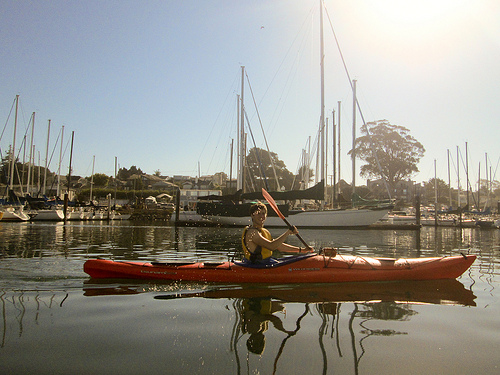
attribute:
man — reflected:
[236, 201, 317, 263]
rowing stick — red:
[264, 182, 314, 254]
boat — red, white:
[84, 250, 480, 284]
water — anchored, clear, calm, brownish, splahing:
[7, 210, 499, 374]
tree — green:
[356, 112, 431, 229]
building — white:
[167, 172, 225, 207]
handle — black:
[283, 217, 312, 249]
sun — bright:
[306, 5, 500, 71]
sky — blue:
[1, 2, 500, 196]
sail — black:
[202, 182, 328, 205]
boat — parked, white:
[184, 177, 398, 231]